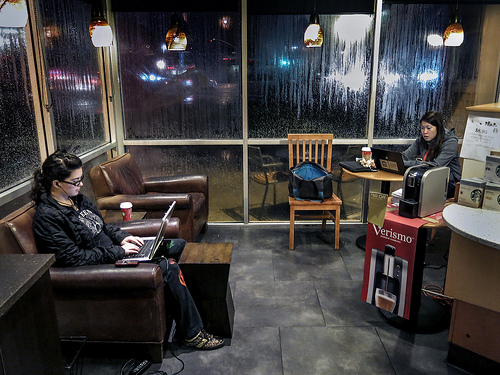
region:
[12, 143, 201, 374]
a woman sitting on a chair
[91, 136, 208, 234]
a brown leather chair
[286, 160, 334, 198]
Purse sitting on chair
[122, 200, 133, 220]
Red cup sitting on arm of chair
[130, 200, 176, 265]
Laptop in woman's lap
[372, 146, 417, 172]
Black laptop on table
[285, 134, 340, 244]
Brown chair on stone floor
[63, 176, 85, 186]
Glasses on girl's face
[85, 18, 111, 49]
Bright hanging light in room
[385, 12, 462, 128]
Window glass covered with rain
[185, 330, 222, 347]
Black and tan shoes on girl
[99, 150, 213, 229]
Brown leather chair near window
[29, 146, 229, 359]
Woman using laptop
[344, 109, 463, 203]
Woman seated at the table using a laptop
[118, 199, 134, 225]
Paper cup of coffee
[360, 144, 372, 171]
Paper coffee cup on the table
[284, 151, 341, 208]
Open black bag on the chair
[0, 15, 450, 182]
Pouring rain seen outside the window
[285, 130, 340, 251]
Wooden chair against the window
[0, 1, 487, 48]
Lights hanging from ceiling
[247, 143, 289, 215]
Chair on the outside patio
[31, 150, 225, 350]
a woman wearing a black jacket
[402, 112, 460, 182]
a woman wearing a grey jacket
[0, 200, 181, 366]
a large brown leather chair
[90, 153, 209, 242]
a large brown leather chair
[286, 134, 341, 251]
a light colored wooden chair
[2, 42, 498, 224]
glass windows with rain on outside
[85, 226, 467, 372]
the grey tile on the study floor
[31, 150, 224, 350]
a girl wearing black glasses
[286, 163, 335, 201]
a black and blue bag on the chair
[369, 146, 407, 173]
a laptop computer on the table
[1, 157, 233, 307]
woman sitting down with a laptop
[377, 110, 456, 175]
woman sitting down with a laptop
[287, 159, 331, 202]
bag on chair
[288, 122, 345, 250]
wooden chair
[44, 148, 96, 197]
woman is wearing eye glasses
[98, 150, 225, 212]
leather love seat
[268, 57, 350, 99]
window is wet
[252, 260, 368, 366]
brick set tile formation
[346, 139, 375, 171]
red coffee cup on table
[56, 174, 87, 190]
woman is wearing glasses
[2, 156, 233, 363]
woman is sitting on a chair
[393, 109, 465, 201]
woman is sitting on a chair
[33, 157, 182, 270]
laptop is on woman lap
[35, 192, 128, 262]
woman has a black jacket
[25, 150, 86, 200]
woman has long hair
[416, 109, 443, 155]
woman has long hair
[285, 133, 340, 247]
bag is on the chair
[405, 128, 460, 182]
woman is wearing a hoodie